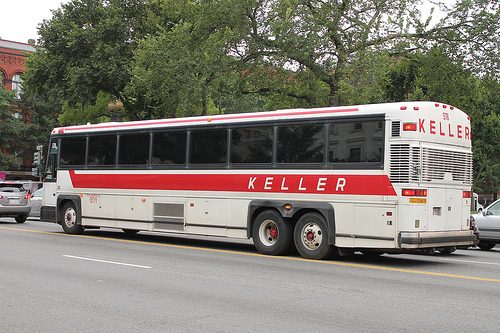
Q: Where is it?
A: This is at the city.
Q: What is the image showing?
A: It is showing a city.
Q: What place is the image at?
A: It is at the city.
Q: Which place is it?
A: It is a city.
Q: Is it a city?
A: Yes, it is a city.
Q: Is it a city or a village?
A: It is a city.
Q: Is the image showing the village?
A: No, the picture is showing the city.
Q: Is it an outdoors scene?
A: Yes, it is outdoors.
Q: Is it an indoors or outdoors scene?
A: It is outdoors.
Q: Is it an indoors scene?
A: No, it is outdoors.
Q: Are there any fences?
A: No, there are no fences.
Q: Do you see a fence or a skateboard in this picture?
A: No, there are no fences or skateboards.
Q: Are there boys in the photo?
A: No, there are no boys.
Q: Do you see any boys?
A: No, there are no boys.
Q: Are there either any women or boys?
A: No, there are no boys or women.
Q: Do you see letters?
A: Yes, there are letters.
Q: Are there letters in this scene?
A: Yes, there are letters.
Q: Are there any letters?
A: Yes, there are letters.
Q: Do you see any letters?
A: Yes, there are letters.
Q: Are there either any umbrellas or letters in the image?
A: Yes, there are letters.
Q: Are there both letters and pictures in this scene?
A: No, there are letters but no pictures.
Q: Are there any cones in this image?
A: No, there are no cones.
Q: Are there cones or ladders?
A: No, there are no cones or ladders.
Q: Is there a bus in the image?
A: Yes, there is a bus.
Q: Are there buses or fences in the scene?
A: Yes, there is a bus.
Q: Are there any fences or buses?
A: Yes, there is a bus.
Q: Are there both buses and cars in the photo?
A: Yes, there are both a bus and a car.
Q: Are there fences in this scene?
A: No, there are no fences.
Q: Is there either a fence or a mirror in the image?
A: No, there are no fences or mirrors.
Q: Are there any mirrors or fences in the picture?
A: No, there are no fences or mirrors.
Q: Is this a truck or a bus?
A: This is a bus.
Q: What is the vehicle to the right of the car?
A: The vehicle is a bus.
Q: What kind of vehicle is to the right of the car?
A: The vehicle is a bus.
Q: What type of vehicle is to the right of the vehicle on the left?
A: The vehicle is a bus.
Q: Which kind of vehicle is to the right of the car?
A: The vehicle is a bus.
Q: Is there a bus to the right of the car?
A: Yes, there is a bus to the right of the car.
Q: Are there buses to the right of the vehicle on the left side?
A: Yes, there is a bus to the right of the car.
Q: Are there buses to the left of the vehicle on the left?
A: No, the bus is to the right of the car.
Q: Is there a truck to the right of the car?
A: No, there is a bus to the right of the car.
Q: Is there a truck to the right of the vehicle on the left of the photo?
A: No, there is a bus to the right of the car.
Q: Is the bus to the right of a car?
A: Yes, the bus is to the right of a car.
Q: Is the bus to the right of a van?
A: No, the bus is to the right of a car.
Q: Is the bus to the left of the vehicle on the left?
A: No, the bus is to the right of the car.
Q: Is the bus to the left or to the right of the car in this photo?
A: The bus is to the right of the car.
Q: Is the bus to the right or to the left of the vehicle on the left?
A: The bus is to the right of the car.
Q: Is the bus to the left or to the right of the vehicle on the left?
A: The bus is to the right of the car.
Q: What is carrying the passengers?
A: The bus is carrying the passengers.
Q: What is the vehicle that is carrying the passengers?
A: The vehicle is a bus.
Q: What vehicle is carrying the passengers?
A: The vehicle is a bus.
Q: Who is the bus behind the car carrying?
A: The bus is carrying passengers.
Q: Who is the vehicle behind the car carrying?
A: The bus is carrying passengers.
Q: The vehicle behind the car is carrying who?
A: The bus is carrying passengers.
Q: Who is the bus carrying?
A: The bus is carrying passengers.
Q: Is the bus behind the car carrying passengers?
A: Yes, the bus is carrying passengers.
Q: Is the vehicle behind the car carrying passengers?
A: Yes, the bus is carrying passengers.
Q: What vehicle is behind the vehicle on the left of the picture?
A: The vehicle is a bus.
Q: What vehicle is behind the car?
A: The vehicle is a bus.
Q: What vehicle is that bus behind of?
A: The bus is behind the car.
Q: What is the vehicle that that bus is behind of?
A: The vehicle is a car.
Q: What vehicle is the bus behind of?
A: The bus is behind the car.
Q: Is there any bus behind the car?
A: Yes, there is a bus behind the car.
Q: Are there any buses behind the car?
A: Yes, there is a bus behind the car.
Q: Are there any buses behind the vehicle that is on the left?
A: Yes, there is a bus behind the car.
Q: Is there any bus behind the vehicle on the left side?
A: Yes, there is a bus behind the car.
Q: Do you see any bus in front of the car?
A: No, the bus is behind the car.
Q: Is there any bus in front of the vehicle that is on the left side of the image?
A: No, the bus is behind the car.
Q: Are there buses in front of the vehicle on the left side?
A: No, the bus is behind the car.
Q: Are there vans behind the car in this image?
A: No, there is a bus behind the car.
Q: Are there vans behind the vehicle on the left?
A: No, there is a bus behind the car.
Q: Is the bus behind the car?
A: Yes, the bus is behind the car.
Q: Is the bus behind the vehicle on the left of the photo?
A: Yes, the bus is behind the car.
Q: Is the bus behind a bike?
A: No, the bus is behind the car.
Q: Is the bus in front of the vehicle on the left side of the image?
A: No, the bus is behind the car.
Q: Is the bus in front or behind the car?
A: The bus is behind the car.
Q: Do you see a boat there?
A: No, there are no boats.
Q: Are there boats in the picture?
A: No, there are no boats.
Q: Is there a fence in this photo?
A: No, there are no fences.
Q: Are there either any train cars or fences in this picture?
A: No, there are no fences or train cars.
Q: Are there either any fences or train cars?
A: No, there are no fences or train cars.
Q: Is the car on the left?
A: Yes, the car is on the left of the image.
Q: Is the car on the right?
A: No, the car is on the left of the image.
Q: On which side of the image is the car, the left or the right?
A: The car is on the left of the image.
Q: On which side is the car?
A: The car is on the left of the image.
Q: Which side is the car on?
A: The car is on the left of the image.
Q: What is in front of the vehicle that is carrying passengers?
A: The car is in front of the bus.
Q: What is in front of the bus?
A: The car is in front of the bus.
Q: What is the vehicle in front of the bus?
A: The vehicle is a car.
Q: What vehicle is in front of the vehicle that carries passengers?
A: The vehicle is a car.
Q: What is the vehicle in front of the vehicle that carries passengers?
A: The vehicle is a car.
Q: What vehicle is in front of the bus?
A: The vehicle is a car.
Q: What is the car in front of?
A: The car is in front of the bus.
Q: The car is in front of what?
A: The car is in front of the bus.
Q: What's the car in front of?
A: The car is in front of the bus.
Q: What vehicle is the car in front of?
A: The car is in front of the bus.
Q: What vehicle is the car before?
A: The car is in front of the bus.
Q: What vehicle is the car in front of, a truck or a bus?
A: The car is in front of a bus.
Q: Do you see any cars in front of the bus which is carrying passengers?
A: Yes, there is a car in front of the bus.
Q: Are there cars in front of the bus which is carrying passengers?
A: Yes, there is a car in front of the bus.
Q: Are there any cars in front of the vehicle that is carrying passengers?
A: Yes, there is a car in front of the bus.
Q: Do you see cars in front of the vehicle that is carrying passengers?
A: Yes, there is a car in front of the bus.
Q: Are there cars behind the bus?
A: No, the car is in front of the bus.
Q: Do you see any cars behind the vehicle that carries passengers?
A: No, the car is in front of the bus.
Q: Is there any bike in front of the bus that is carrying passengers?
A: No, there is a car in front of the bus.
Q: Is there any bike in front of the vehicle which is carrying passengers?
A: No, there is a car in front of the bus.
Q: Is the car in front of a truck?
A: No, the car is in front of the bus.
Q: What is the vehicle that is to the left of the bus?
A: The vehicle is a car.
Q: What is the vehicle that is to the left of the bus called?
A: The vehicle is a car.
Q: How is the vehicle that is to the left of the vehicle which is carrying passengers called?
A: The vehicle is a car.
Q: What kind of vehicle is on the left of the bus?
A: The vehicle is a car.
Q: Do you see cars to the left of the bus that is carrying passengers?
A: Yes, there is a car to the left of the bus.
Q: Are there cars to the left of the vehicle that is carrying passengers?
A: Yes, there is a car to the left of the bus.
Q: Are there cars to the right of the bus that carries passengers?
A: No, the car is to the left of the bus.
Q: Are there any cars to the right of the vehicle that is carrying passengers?
A: No, the car is to the left of the bus.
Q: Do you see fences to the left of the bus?
A: No, there is a car to the left of the bus.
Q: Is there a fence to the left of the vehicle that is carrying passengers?
A: No, there is a car to the left of the bus.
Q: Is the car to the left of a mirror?
A: No, the car is to the left of a bus.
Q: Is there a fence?
A: No, there are no fences.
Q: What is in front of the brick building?
A: The trees are in front of the building.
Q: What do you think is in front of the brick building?
A: The trees are in front of the building.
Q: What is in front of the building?
A: The trees are in front of the building.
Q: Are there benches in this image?
A: No, there are no benches.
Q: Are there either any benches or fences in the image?
A: No, there are no benches or fences.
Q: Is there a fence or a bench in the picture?
A: No, there are no benches or fences.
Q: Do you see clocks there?
A: No, there are no clocks.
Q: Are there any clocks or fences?
A: No, there are no clocks or fences.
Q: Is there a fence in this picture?
A: No, there are no fences.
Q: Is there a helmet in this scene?
A: No, there are no helmets.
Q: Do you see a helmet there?
A: No, there are no helmets.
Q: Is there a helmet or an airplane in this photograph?
A: No, there are no helmets or airplanes.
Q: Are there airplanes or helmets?
A: No, there are no helmets or airplanes.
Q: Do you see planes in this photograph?
A: No, there are no planes.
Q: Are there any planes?
A: No, there are no planes.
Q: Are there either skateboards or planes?
A: No, there are no planes or skateboards.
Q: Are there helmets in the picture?
A: No, there are no helmets.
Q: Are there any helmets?
A: No, there are no helmets.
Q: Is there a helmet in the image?
A: No, there are no helmets.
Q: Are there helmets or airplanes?
A: No, there are no helmets or airplanes.